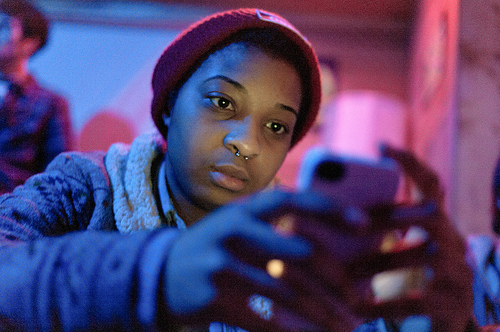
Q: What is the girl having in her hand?
A: Mobile.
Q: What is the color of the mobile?
A: White.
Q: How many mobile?
A: 1.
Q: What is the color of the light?
A: Pink.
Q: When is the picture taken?
A: Night time.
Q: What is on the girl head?
A: Cap.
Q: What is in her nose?
A: Nose rings.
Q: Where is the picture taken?
A: In a public space.